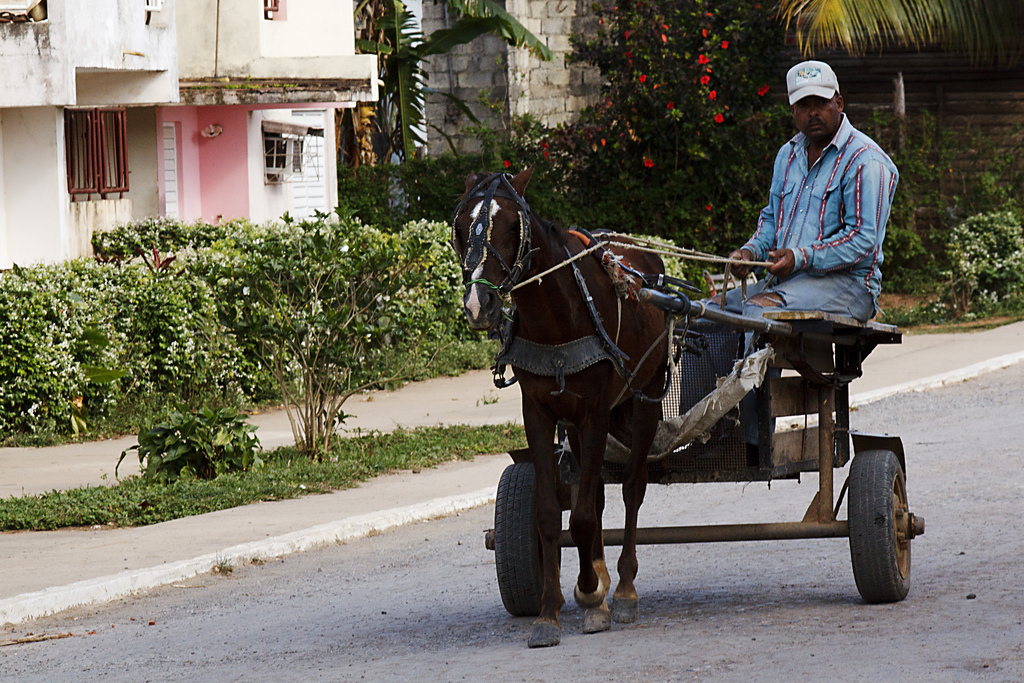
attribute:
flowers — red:
[662, 52, 738, 120]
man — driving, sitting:
[704, 52, 899, 329]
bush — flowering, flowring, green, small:
[49, 241, 563, 441]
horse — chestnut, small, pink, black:
[385, 168, 667, 487]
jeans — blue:
[678, 233, 915, 388]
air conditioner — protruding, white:
[227, 106, 331, 205]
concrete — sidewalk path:
[181, 521, 475, 682]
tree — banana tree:
[337, 0, 594, 214]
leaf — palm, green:
[404, 18, 565, 60]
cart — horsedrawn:
[653, 309, 904, 557]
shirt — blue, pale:
[687, 120, 921, 298]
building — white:
[3, 10, 382, 244]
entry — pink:
[108, 78, 255, 222]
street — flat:
[805, 366, 1015, 572]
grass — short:
[252, 439, 402, 476]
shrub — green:
[23, 250, 221, 442]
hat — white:
[766, 44, 848, 103]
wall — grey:
[404, 0, 604, 150]